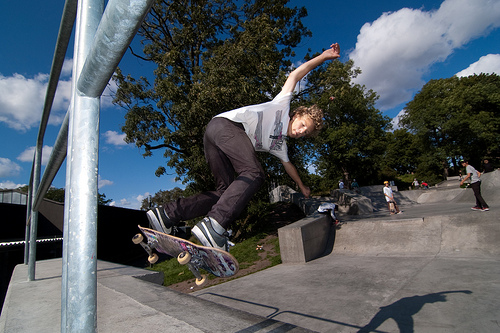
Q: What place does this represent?
A: It represents the skate park.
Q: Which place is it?
A: It is a skate park.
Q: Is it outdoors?
A: Yes, it is outdoors.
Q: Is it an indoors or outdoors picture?
A: It is outdoors.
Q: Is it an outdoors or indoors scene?
A: It is outdoors.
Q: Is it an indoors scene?
A: No, it is outdoors.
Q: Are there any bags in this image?
A: No, there are no bags.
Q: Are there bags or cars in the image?
A: No, there are no bags or cars.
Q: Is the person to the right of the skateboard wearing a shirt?
A: Yes, the person is wearing a shirt.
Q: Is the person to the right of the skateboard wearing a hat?
A: No, the person is wearing a shirt.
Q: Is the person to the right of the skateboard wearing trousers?
A: Yes, the person is wearing trousers.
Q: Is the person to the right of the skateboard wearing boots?
A: No, the person is wearing trousers.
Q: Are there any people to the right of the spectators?
A: Yes, there is a person to the right of the spectators.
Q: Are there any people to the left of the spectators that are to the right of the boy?
A: No, the person is to the right of the spectators.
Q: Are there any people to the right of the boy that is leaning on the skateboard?
A: Yes, there is a person to the right of the boy.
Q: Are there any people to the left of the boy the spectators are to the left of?
A: No, the person is to the right of the boy.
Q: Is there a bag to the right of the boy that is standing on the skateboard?
A: No, there is a person to the right of the boy.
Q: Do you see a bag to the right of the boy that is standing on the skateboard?
A: No, there is a person to the right of the boy.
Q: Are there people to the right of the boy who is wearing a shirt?
A: Yes, there is a person to the right of the boy.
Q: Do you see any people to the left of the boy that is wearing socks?
A: No, the person is to the right of the boy.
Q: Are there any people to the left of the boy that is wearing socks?
A: No, the person is to the right of the boy.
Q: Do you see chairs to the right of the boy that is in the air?
A: No, there is a person to the right of the boy.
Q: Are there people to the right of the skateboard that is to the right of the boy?
A: Yes, there is a person to the right of the skateboard.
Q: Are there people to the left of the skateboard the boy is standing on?
A: No, the person is to the right of the skateboard.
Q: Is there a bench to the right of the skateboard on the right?
A: No, there is a person to the right of the skateboard.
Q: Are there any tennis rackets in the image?
A: No, there are no tennis rackets.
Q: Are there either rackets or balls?
A: No, there are no rackets or balls.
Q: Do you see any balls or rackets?
A: No, there are no rackets or balls.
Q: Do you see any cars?
A: No, there are no cars.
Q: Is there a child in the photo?
A: Yes, there are children.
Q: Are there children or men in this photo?
A: Yes, there are children.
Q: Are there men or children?
A: Yes, there are children.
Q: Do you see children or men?
A: Yes, there are children.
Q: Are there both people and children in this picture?
A: Yes, there are both children and a person.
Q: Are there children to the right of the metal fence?
A: Yes, there are children to the right of the fence.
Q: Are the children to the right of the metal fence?
A: Yes, the children are to the right of the fence.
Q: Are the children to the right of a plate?
A: No, the children are to the right of the fence.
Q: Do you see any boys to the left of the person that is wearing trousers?
A: Yes, there is a boy to the left of the person.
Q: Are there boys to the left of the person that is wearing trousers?
A: Yes, there is a boy to the left of the person.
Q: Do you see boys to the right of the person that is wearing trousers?
A: No, the boy is to the left of the person.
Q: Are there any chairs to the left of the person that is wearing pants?
A: No, there is a boy to the left of the person.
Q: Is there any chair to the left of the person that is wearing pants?
A: No, there is a boy to the left of the person.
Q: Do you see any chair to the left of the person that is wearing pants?
A: No, there is a boy to the left of the person.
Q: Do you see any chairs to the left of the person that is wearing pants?
A: No, there is a boy to the left of the person.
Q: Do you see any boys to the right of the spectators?
A: Yes, there is a boy to the right of the spectators.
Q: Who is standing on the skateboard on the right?
A: The boy is standing on the skateboard.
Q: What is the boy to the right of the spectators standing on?
A: The boy is standing on the skateboard.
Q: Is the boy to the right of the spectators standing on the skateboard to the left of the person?
A: Yes, the boy is standing on the skateboard.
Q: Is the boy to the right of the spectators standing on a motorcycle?
A: No, the boy is standing on the skateboard.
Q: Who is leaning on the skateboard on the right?
A: The boy is leaning on the skateboard.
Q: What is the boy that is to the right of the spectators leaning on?
A: The boy is leaning on the skateboard.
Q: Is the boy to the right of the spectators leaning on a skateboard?
A: Yes, the boy is leaning on a skateboard.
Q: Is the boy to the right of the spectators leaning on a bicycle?
A: No, the boy is leaning on a skateboard.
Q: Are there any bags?
A: No, there are no bags.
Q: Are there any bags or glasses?
A: No, there are no bags or glasses.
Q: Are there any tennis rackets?
A: No, there are no tennis rackets.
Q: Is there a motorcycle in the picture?
A: No, there are no motorcycles.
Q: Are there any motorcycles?
A: No, there are no motorcycles.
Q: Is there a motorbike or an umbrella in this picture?
A: No, there are no motorcycles or umbrellas.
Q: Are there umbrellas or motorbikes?
A: No, there are no motorbikes or umbrellas.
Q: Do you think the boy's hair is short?
A: Yes, the hair is short.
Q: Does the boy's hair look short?
A: Yes, the hair is short.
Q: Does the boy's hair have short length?
A: Yes, the hair is short.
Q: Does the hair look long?
A: No, the hair is short.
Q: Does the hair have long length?
A: No, the hair is short.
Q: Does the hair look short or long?
A: The hair is short.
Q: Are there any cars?
A: No, there are no cars.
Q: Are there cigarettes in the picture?
A: No, there are no cigarettes.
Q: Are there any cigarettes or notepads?
A: No, there are no cigarettes or notepads.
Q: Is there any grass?
A: Yes, there is grass.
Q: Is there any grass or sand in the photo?
A: Yes, there is grass.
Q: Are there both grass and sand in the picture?
A: No, there is grass but no sand.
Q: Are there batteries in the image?
A: No, there are no batteries.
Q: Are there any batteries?
A: No, there are no batteries.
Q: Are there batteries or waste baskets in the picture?
A: No, there are no batteries or waste baskets.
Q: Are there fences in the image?
A: Yes, there is a fence.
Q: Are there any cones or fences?
A: Yes, there is a fence.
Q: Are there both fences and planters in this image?
A: No, there is a fence but no planters.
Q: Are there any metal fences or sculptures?
A: Yes, there is a metal fence.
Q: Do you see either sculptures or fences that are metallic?
A: Yes, the fence is metallic.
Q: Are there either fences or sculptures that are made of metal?
A: Yes, the fence is made of metal.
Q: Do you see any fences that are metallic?
A: Yes, there is a metal fence.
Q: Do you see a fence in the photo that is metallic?
A: Yes, there is a fence that is metallic.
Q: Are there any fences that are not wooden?
A: Yes, there is a metallic fence.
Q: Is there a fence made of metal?
A: Yes, there is a fence that is made of metal.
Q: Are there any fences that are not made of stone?
A: Yes, there is a fence that is made of metal.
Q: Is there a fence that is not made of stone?
A: Yes, there is a fence that is made of metal.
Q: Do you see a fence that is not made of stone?
A: Yes, there is a fence that is made of metal.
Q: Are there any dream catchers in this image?
A: No, there are no dream catchers.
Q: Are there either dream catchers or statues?
A: No, there are no dream catchers or statues.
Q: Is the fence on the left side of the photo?
A: Yes, the fence is on the left of the image.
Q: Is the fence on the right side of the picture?
A: No, the fence is on the left of the image.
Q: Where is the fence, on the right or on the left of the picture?
A: The fence is on the left of the image.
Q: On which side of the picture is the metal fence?
A: The fence is on the left of the image.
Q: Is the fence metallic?
A: Yes, the fence is metallic.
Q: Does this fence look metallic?
A: Yes, the fence is metallic.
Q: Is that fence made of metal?
A: Yes, the fence is made of metal.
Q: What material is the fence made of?
A: The fence is made of metal.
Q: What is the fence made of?
A: The fence is made of metal.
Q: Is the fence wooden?
A: No, the fence is metallic.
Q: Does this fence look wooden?
A: No, the fence is metallic.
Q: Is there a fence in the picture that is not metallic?
A: No, there is a fence but it is metallic.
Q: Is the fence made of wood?
A: No, the fence is made of metal.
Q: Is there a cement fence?
A: No, there is a fence but it is made of metal.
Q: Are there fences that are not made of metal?
A: No, there is a fence but it is made of metal.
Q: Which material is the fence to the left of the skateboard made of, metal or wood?
A: The fence is made of metal.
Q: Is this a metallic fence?
A: Yes, this is a metallic fence.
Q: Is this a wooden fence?
A: No, this is a metallic fence.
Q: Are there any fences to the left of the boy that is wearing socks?
A: Yes, there is a fence to the left of the boy.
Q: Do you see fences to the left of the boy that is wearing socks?
A: Yes, there is a fence to the left of the boy.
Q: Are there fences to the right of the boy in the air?
A: No, the fence is to the left of the boy.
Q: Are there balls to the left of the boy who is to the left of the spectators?
A: No, there is a fence to the left of the boy.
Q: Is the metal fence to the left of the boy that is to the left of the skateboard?
A: Yes, the fence is to the left of the boy.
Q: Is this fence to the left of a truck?
A: No, the fence is to the left of the boy.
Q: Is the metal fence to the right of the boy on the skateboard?
A: No, the fence is to the left of the boy.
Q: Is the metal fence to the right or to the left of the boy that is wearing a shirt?
A: The fence is to the left of the boy.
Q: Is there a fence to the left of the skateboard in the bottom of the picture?
A: Yes, there is a fence to the left of the skateboard.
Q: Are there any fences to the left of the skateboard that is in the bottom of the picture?
A: Yes, there is a fence to the left of the skateboard.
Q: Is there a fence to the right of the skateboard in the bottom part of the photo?
A: No, the fence is to the left of the skateboard.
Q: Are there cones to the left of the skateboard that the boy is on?
A: No, there is a fence to the left of the skateboard.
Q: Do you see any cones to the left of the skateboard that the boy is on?
A: No, there is a fence to the left of the skateboard.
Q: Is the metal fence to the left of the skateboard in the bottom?
A: Yes, the fence is to the left of the skateboard.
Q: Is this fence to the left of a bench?
A: No, the fence is to the left of the skateboard.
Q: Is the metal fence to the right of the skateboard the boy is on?
A: No, the fence is to the left of the skateboard.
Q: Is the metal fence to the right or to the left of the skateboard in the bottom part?
A: The fence is to the left of the skateboard.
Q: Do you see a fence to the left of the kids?
A: Yes, there is a fence to the left of the kids.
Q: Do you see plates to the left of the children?
A: No, there is a fence to the left of the children.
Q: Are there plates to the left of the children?
A: No, there is a fence to the left of the children.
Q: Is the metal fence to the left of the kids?
A: Yes, the fence is to the left of the kids.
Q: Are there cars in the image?
A: No, there are no cars.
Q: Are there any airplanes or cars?
A: No, there are no cars or airplanes.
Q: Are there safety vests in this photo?
A: No, there are no safety vests.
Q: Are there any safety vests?
A: No, there are no safety vests.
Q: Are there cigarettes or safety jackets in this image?
A: No, there are no safety jackets or cigarettes.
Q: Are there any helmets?
A: Yes, there is a helmet.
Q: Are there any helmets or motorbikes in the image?
A: Yes, there is a helmet.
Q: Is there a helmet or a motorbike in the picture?
A: Yes, there is a helmet.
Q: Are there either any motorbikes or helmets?
A: Yes, there is a helmet.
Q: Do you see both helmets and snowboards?
A: No, there is a helmet but no snowboards.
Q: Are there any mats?
A: No, there are no mats.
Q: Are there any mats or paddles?
A: No, there are no mats or paddles.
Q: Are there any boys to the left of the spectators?
A: Yes, there is a boy to the left of the spectators.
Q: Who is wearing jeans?
A: The boy is wearing jeans.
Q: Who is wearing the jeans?
A: The boy is wearing jeans.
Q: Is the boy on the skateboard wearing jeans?
A: Yes, the boy is wearing jeans.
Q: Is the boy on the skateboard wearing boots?
A: No, the boy is wearing jeans.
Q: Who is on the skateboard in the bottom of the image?
A: The boy is on the skateboard.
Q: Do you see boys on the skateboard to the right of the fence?
A: Yes, there is a boy on the skateboard.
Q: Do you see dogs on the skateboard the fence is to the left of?
A: No, there is a boy on the skateboard.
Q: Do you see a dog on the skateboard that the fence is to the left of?
A: No, there is a boy on the skateboard.